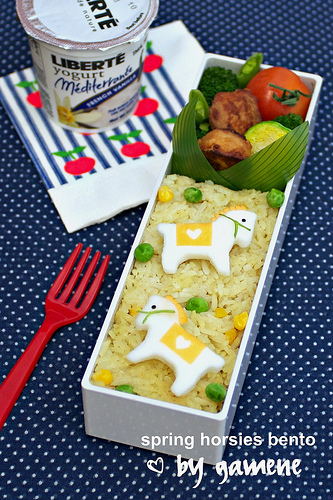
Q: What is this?
A: Assorted dinner.